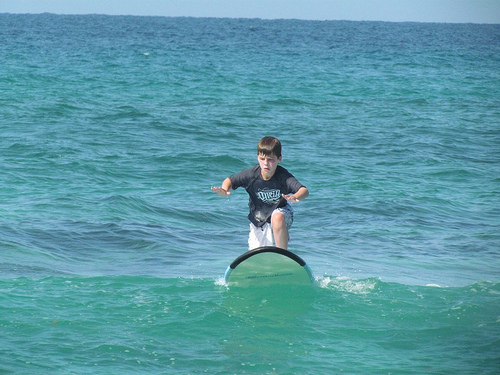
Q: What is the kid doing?
A: Surfing.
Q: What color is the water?
A: Blue.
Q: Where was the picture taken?
A: The ocean.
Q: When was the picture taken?
A: During the day.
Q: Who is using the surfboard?
A: The boy.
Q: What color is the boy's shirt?
A: Black.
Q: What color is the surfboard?
A: White and black.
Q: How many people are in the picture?
A: 1.